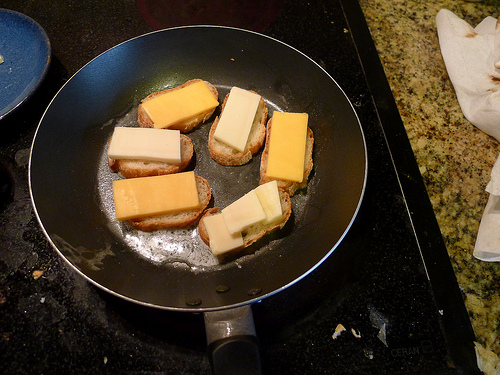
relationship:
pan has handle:
[17, 35, 354, 342] [176, 310, 256, 365]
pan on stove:
[25, 22, 369, 375] [3, 1, 471, 373]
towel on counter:
[437, 10, 499, 264] [358, 0, 498, 373]